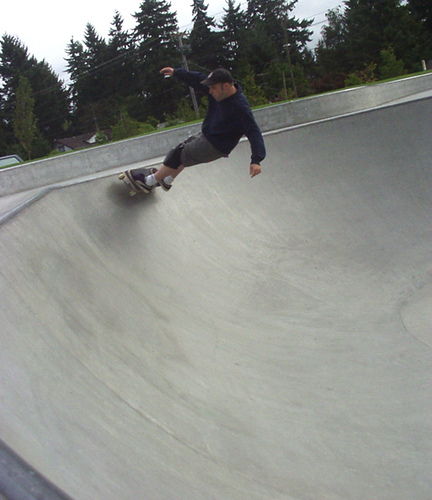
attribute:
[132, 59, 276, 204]
man — wearing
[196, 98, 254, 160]
sweatshirt — blue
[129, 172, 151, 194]
shoe — burgundy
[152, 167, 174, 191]
shoe — burgundy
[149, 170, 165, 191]
sole — tan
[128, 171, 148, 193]
sole — tan